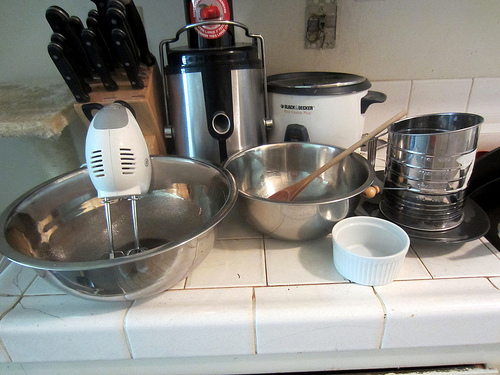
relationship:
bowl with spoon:
[223, 141, 378, 242] [262, 108, 421, 206]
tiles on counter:
[0, 212, 497, 374] [0, 212, 499, 372]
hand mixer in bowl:
[84, 102, 153, 277] [2, 151, 239, 303]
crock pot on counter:
[263, 70, 387, 155] [0, 190, 498, 374]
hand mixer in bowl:
[81, 98, 155, 258] [2, 151, 239, 303]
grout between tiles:
[215, 239, 309, 301] [208, 235, 349, 355]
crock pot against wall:
[266, 71, 387, 155] [4, 0, 483, 96]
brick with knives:
[72, 61, 164, 152] [41, 0, 149, 89]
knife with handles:
[47, 43, 91, 104] [65, 21, 139, 83]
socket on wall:
[302, 1, 338, 49] [5, 4, 480, 80]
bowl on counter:
[331, 210, 412, 286] [28, 140, 484, 368]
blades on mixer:
[103, 197, 146, 258] [83, 101, 153, 203]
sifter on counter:
[375, 109, 484, 232] [28, 140, 484, 368]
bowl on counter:
[228, 138, 379, 244] [5, 154, 478, 369]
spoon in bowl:
[266, 108, 409, 201] [228, 138, 379, 244]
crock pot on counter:
[266, 71, 387, 155] [0, 127, 480, 372]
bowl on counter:
[2, 151, 239, 303] [0, 127, 480, 372]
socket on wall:
[302, 1, 338, 47] [4, 0, 483, 96]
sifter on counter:
[378, 110, 485, 231] [0, 144, 499, 374]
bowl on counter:
[331, 210, 412, 286] [5, 154, 478, 369]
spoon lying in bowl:
[261, 109, 409, 200] [228, 138, 379, 244]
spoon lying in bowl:
[261, 109, 409, 200] [222, 139, 373, 242]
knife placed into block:
[47, 43, 91, 104] [72, 59, 169, 157]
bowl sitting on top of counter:
[331, 215, 411, 286] [1, 204, 483, 363]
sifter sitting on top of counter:
[375, 109, 484, 232] [1, 204, 483, 363]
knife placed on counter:
[47, 43, 91, 104] [71, 59, 171, 156]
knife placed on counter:
[84, 15, 115, 66] [71, 59, 171, 156]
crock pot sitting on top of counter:
[263, 70, 387, 155] [1, 204, 483, 363]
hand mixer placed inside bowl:
[84, 102, 153, 277] [2, 151, 239, 303]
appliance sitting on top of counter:
[156, 15, 275, 166] [1, 204, 483, 363]